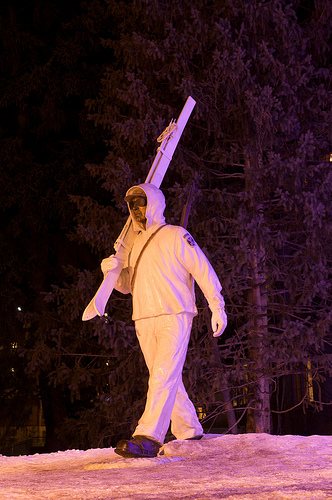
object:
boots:
[114, 434, 159, 459]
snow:
[1, 453, 332, 500]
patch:
[181, 233, 197, 249]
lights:
[17, 306, 22, 312]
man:
[101, 183, 226, 458]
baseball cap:
[123, 189, 146, 200]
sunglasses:
[128, 197, 147, 208]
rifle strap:
[130, 186, 199, 295]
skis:
[82, 95, 197, 321]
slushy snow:
[204, 433, 332, 500]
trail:
[0, 435, 330, 499]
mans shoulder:
[80, 226, 142, 322]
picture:
[2, 1, 332, 500]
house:
[200, 354, 331, 433]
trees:
[0, 0, 97, 449]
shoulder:
[172, 223, 204, 261]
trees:
[209, 2, 331, 433]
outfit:
[99, 182, 228, 438]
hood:
[123, 183, 167, 232]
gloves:
[208, 309, 229, 337]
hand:
[211, 309, 226, 337]